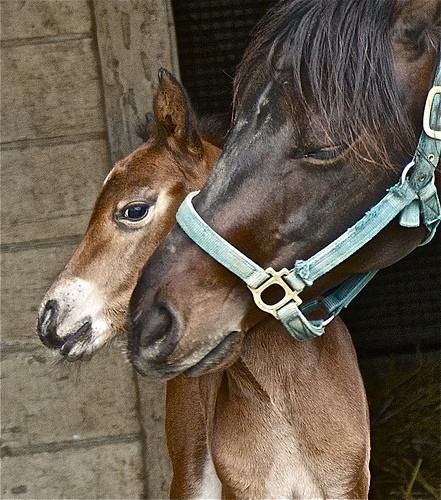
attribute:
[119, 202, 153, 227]
eye — black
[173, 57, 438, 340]
bridle — green, blue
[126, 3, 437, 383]
horse — brown, nuzzling, dark, baby, large, affectionate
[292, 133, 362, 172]
eye — closed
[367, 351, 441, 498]
straw — lain, laid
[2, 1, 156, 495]
boards — tan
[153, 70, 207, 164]
ear — brown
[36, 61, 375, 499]
calf — brown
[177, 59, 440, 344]
reigns — blue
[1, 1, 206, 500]
wall — stable, boarded, tan, wooden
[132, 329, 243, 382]
mouth — large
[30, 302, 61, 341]
nose — white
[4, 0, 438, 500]
barn — wooden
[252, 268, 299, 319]
harness — gold